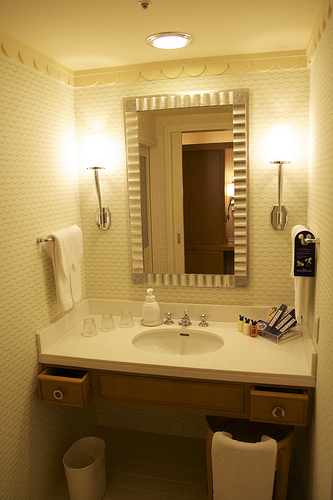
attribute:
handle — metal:
[271, 405, 287, 419]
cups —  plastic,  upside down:
[80, 295, 132, 341]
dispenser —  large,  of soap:
[135, 278, 164, 328]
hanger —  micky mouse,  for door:
[292, 223, 313, 276]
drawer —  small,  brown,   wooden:
[249, 382, 309, 429]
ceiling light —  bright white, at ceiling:
[148, 33, 192, 50]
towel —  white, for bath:
[24, 231, 107, 303]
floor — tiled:
[48, 423, 228, 499]